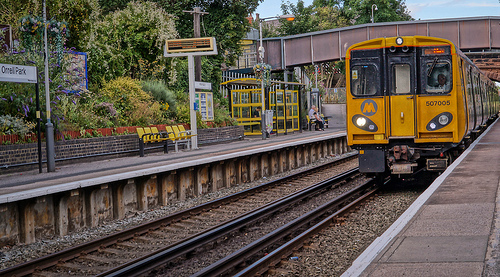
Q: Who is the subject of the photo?
A: The train.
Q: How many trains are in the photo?
A: One.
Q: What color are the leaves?
A: Green.